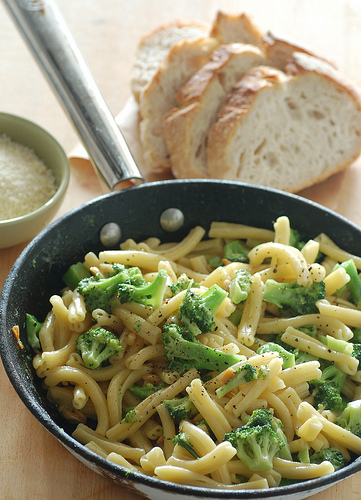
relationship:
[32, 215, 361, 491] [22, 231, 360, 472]
macaroni with broccoli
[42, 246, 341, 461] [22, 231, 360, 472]
pepper on broccoli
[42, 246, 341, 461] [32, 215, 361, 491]
pepper on macaroni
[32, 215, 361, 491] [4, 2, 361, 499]
macaroni in pan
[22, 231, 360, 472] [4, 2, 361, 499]
broccoli in pan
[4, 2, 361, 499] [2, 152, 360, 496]
pan on counter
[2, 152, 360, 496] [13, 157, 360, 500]
counter made of wood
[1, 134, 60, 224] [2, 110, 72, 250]
rice in bowl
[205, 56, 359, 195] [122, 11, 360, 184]
slice of bread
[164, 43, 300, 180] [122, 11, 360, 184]
slice of bread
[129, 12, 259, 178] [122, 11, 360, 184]
slice of bread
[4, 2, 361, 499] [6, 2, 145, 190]
pan has handle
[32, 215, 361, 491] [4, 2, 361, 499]
pasta in pan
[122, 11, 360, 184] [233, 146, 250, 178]
bread has holes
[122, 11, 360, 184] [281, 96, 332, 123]
bread has holes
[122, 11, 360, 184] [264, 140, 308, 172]
bread has holes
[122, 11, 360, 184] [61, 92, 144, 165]
bread on napkin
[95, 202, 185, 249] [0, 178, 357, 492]
bolts in pot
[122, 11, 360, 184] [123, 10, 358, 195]
bread has crust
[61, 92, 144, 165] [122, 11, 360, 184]
napkin beneath bread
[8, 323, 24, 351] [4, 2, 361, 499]
garlic on pan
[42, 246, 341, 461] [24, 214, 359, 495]
pepper on top of dish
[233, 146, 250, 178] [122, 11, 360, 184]
holes in bread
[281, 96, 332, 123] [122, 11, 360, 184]
holes in bread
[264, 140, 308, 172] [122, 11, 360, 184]
holes in bread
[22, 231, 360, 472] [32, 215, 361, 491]
broccoli mixed with macaroni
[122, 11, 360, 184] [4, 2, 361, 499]
bread beside pan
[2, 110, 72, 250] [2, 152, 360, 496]
bowl on counter